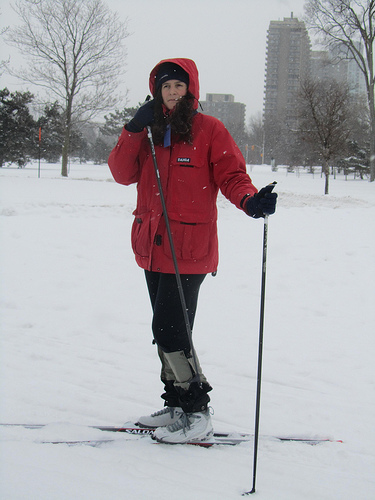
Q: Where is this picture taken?
A: On a snow covered field.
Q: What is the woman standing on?
A: Skis.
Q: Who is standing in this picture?
A: A woman.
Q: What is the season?
A: Winter.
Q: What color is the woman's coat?
A: Red.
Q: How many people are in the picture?
A: One.